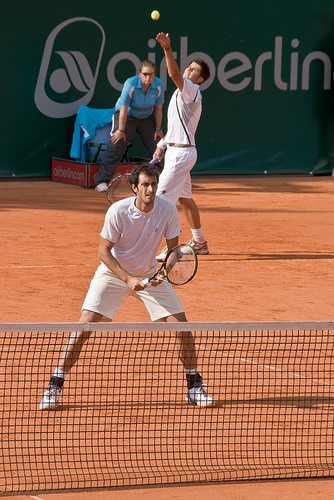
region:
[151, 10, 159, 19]
green tennis ball in air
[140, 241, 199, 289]
black and white tennis racquet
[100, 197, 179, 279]
white cotton tee shorts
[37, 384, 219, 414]
grey and white sneakers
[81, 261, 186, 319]
white cotton tennis shorts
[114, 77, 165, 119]
turquoise blue polo shirt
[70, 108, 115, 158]
blue jacket on chair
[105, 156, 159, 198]
tennis racquet in hand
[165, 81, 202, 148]
white and grey tee shirt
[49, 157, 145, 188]
red painted wood platform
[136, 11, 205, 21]
ball in the air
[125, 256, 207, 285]
racquet in the right hand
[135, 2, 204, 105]
arm catching the ball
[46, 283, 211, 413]
legs apart in a stance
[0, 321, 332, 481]
net seperating the players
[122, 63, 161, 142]
person with hands on knees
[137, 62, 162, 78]
sunglasses on the face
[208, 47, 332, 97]
large white lettering on the sign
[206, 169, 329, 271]
shadows on the court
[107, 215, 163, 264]
white shirt on the player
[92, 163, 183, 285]
this is a tennis player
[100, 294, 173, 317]
these are the legs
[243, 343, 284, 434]
this is a net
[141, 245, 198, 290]
this is a racket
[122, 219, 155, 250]
this is the t shirt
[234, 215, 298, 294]
this is the pitch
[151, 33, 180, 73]
this is the hand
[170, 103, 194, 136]
the jersey is white in color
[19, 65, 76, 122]
this is a poster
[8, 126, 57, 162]
it is green in color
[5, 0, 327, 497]
two man playing tennis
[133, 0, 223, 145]
tennis player throwing a ball in the air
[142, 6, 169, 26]
the ball is in the air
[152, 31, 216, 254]
tennis player wears white clothes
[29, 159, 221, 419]
tennis player wears white clothes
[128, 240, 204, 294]
a racket color black and white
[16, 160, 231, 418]
tennis player is bend forward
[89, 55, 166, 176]
man wears blue shirt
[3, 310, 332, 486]
net to play tennis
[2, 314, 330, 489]
white border of net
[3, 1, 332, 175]
green wall with white logo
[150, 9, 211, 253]
man throwing ball in the air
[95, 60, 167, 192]
woman leaning forward over court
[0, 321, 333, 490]
net with black string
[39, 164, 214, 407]
tennis player in ready stance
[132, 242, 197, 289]
tennis racket in hand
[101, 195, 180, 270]
white short sleeved tee shirt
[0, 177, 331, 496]
surface of clay court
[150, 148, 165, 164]
hand on racket grip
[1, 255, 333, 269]
white line on court